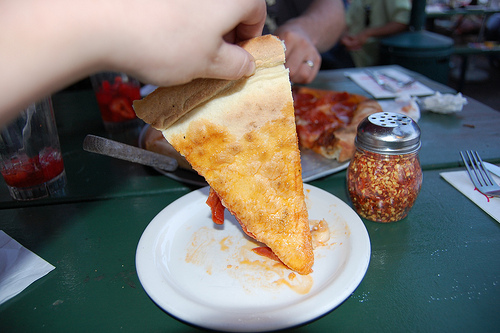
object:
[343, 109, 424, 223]
bottle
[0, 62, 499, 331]
table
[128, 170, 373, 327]
plate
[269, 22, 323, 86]
left hand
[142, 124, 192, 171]
pizza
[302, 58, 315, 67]
ring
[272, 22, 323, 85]
hand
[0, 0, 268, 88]
hand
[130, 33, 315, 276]
pizza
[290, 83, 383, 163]
pizza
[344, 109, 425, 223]
pepper shaker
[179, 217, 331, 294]
juice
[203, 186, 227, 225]
toppings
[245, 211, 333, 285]
toppings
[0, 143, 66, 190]
beverage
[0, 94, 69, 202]
glass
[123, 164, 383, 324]
plate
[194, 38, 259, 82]
thumb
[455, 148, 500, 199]
fork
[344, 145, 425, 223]
flakes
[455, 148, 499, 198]
fork head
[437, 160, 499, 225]
napkin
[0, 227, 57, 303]
napkin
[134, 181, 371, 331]
plate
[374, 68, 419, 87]
silverware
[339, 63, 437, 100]
napkin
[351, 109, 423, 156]
top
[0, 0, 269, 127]
person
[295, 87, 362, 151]
pepperoni